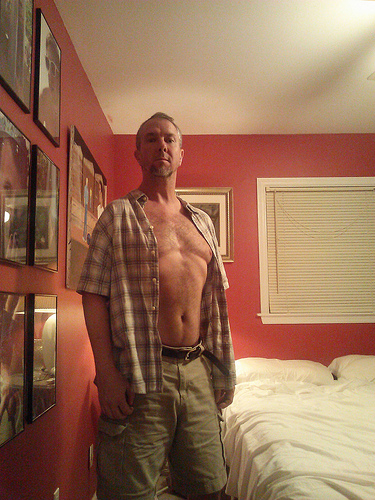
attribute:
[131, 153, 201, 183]
bear —   Short,  man's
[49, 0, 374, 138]
ceiling —  White ,  visible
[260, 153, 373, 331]
windowframe —  white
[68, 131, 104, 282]
frame —  for picture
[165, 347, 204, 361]
belt —  Brown,   leather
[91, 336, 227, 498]
shorts —  Khaki,  man's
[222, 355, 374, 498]
bed sheets —  White, for bed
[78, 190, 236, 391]
shirt — unbuttoned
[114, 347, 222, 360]
waist —  man's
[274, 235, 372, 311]
blinds —  white